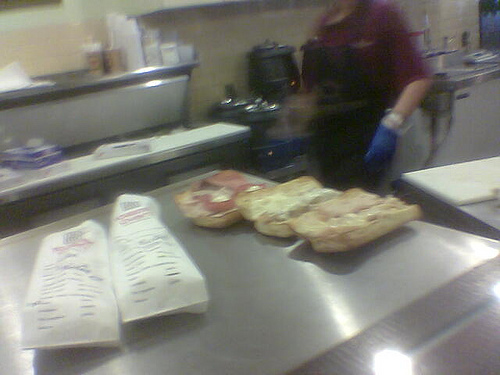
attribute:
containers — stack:
[115, 17, 147, 71]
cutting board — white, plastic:
[401, 152, 498, 208]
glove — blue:
[364, 124, 406, 171]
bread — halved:
[289, 188, 422, 256]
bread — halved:
[238, 174, 338, 241]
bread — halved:
[174, 166, 260, 231]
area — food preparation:
[1, 120, 248, 194]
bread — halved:
[289, 190, 421, 250]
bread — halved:
[184, 166, 264, 227]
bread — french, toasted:
[177, 157, 422, 253]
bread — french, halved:
[192, 151, 412, 271]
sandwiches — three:
[174, 161, 424, 257]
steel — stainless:
[204, 232, 499, 369]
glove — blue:
[355, 105, 418, 185]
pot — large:
[246, 41, 302, 96]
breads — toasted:
[171, 166, 425, 252]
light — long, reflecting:
[287, 237, 362, 340]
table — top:
[3, 167, 498, 374]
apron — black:
[305, 33, 390, 193]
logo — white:
[351, 33, 376, 49]